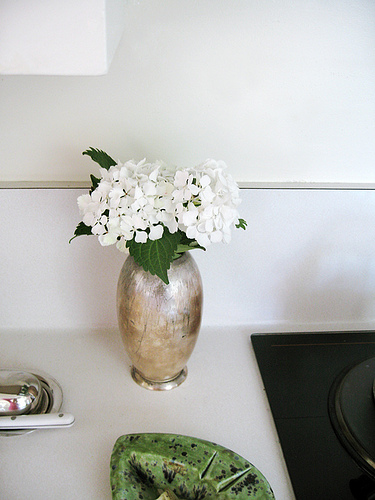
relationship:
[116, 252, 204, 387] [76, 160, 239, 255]
vase with flowers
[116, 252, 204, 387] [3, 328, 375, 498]
vase on counter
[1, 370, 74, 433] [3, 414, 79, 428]
dish contains flatware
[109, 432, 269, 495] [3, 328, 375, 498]
ashtray on counter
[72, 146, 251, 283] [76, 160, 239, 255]
plant has flowers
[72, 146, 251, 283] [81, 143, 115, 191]
plant has leaves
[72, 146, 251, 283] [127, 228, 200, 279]
plant has leaves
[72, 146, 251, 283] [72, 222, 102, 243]
plant has leaves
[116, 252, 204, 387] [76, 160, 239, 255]
vase holds flowers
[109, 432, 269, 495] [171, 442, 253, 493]
dish has spots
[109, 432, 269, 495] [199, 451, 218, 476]
dish has indent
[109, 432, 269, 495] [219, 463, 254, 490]
dish has indent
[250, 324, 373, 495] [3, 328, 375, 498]
panel on counter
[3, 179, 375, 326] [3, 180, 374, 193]
backsplash has edge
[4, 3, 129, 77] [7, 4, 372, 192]
cube on wall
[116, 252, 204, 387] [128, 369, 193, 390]
vase has base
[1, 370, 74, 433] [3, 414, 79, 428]
dish holds flatware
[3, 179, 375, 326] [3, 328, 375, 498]
backsplash for counter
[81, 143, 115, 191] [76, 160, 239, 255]
leaves out of flowers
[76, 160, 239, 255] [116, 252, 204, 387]
flowers in vase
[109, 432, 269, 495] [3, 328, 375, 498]
dish on counter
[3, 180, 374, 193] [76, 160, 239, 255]
edge behind flowers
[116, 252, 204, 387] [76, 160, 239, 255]
vase of flowers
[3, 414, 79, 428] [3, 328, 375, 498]
flatware on counter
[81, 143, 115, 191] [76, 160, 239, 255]
leaves behind flowers